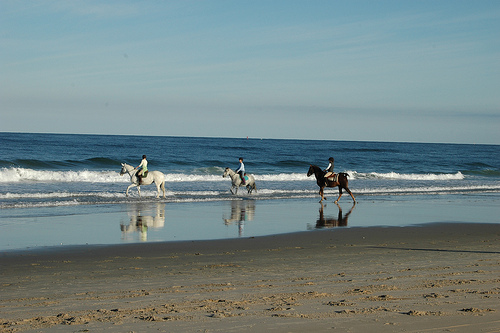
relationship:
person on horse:
[133, 154, 148, 187] [120, 162, 168, 197]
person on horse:
[235, 157, 246, 182] [221, 167, 256, 195]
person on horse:
[321, 154, 334, 192] [306, 164, 357, 207]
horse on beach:
[120, 162, 168, 197] [0, 186, 496, 329]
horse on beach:
[221, 167, 256, 195] [0, 186, 496, 329]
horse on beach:
[306, 164, 357, 207] [0, 186, 496, 329]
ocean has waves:
[0, 131, 499, 188] [4, 154, 469, 189]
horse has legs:
[120, 162, 168, 197] [123, 182, 165, 197]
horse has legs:
[221, 167, 256, 195] [229, 185, 256, 194]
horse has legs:
[306, 164, 357, 207] [315, 186, 356, 205]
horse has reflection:
[120, 162, 168, 197] [116, 201, 165, 241]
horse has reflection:
[221, 167, 256, 195] [219, 197, 257, 232]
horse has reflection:
[306, 164, 357, 207] [308, 200, 356, 230]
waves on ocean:
[4, 154, 469, 189] [0, 131, 499, 188]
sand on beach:
[3, 225, 499, 331] [0, 186, 496, 329]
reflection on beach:
[308, 200, 356, 230] [0, 186, 496, 329]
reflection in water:
[116, 201, 165, 241] [2, 202, 495, 249]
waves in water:
[4, 154, 469, 189] [0, 131, 499, 188]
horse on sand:
[120, 162, 168, 197] [3, 225, 499, 331]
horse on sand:
[221, 167, 256, 195] [3, 225, 499, 331]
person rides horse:
[133, 154, 148, 187] [120, 162, 168, 197]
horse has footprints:
[120, 162, 168, 197] [45, 294, 290, 321]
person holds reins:
[133, 154, 148, 187] [132, 165, 138, 178]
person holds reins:
[235, 157, 246, 182] [233, 170, 238, 182]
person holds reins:
[321, 154, 334, 192] [317, 169, 327, 177]